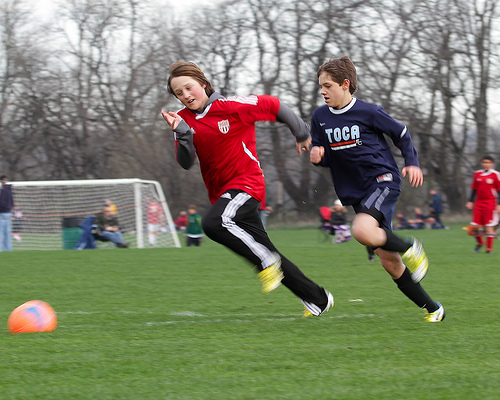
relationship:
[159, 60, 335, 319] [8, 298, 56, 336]
boy chasing soccer ball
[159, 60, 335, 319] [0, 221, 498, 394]
boy on top of field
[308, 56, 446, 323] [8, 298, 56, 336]
boy running after soccer ball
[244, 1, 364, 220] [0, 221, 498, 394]
tree on top of field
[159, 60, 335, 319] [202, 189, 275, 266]
boy has leg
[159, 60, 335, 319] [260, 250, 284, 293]
boy has shoe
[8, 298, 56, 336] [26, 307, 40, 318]
soccer ball has spot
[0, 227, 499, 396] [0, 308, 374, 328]
grass has line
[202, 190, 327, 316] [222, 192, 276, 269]
pants have stripe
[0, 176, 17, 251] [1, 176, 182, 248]
man next to soccer net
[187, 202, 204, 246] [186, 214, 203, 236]
person wearing shirt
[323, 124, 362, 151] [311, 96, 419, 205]
logo on top of jersey